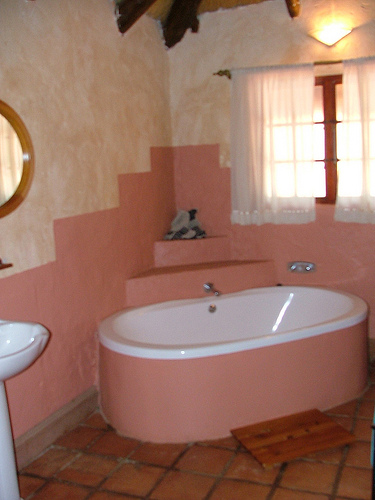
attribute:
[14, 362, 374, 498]
floor — brown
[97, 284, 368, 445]
bathtub — pink, white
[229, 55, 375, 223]
curtain — sheer, white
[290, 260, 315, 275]
knobs — here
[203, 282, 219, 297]
spout — chrome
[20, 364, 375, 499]
tiles — brown, stained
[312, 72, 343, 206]
frame — wood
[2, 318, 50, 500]
sink — porcelain, white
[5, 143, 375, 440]
surround — pink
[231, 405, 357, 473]
mat — orange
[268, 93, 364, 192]
light — shining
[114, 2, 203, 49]
beams — wooden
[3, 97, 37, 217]
mirror — wood, round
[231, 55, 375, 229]
curtains — white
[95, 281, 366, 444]
tub — white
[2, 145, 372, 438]
enclosure — pink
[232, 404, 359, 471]
step — wooden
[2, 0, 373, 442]
walls — different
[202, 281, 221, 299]
faucet — silver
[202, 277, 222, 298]
tap — silver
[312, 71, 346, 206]
pane — brown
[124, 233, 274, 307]
steps — pink